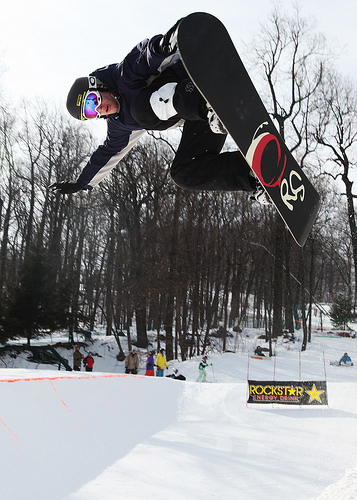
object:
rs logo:
[279, 171, 306, 213]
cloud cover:
[0, 0, 356, 278]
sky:
[0, 1, 356, 265]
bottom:
[175, 10, 323, 248]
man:
[46, 17, 272, 206]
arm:
[76, 120, 146, 190]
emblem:
[244, 120, 287, 189]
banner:
[246, 379, 328, 406]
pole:
[272, 349, 276, 408]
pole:
[298, 349, 303, 408]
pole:
[244, 349, 248, 403]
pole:
[321, 349, 326, 380]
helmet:
[64, 75, 107, 121]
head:
[63, 75, 120, 120]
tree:
[303, 61, 355, 299]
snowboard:
[175, 11, 322, 247]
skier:
[83, 349, 95, 372]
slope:
[0, 367, 186, 499]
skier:
[335, 348, 351, 364]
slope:
[179, 303, 356, 381]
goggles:
[81, 84, 103, 122]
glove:
[44, 181, 86, 200]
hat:
[64, 74, 87, 123]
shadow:
[140, 437, 277, 472]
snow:
[0, 304, 356, 499]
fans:
[154, 345, 168, 377]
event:
[246, 381, 329, 407]